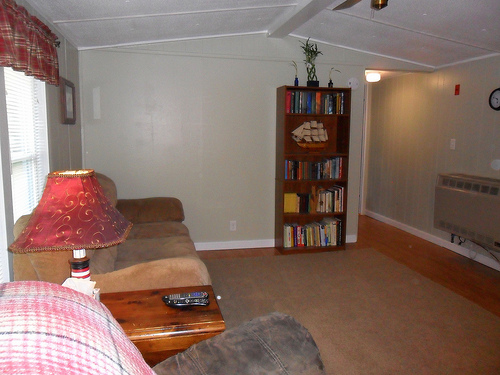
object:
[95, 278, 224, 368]
table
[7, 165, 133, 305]
lamp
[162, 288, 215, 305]
remote controls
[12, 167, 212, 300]
sofa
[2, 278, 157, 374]
blanket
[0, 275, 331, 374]
chair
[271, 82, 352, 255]
bookshelf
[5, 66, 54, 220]
blinds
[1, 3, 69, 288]
window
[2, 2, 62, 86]
material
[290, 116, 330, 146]
ship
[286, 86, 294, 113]
books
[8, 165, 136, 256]
lampshade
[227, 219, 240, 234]
outlet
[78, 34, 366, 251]
wall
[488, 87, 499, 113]
clock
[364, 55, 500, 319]
wall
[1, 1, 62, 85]
valance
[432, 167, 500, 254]
heater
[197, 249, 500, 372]
rug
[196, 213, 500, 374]
floor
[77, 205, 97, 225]
swirls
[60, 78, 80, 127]
picture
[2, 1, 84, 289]
wall